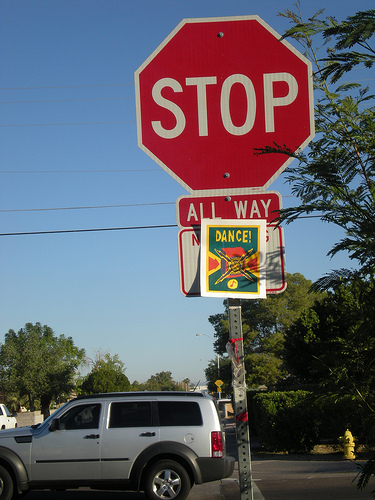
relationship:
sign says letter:
[133, 10, 317, 192] [151, 72, 298, 139]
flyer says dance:
[199, 216, 269, 302] [213, 227, 253, 245]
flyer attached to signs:
[199, 216, 269, 302] [174, 190, 290, 295]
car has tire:
[1, 387, 237, 499] [139, 456, 193, 499]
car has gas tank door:
[1, 387, 237, 499] [181, 430, 197, 445]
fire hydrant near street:
[336, 427, 358, 463] [237, 455, 373, 500]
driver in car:
[84, 405, 100, 430] [1, 387, 237, 499]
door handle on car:
[82, 432, 102, 441] [1, 387, 237, 499]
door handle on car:
[138, 430, 158, 440] [1, 387, 237, 499]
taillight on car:
[210, 430, 222, 460] [1, 387, 237, 499]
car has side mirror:
[1, 387, 237, 499] [45, 414, 63, 432]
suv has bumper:
[1, 387, 237, 499] [194, 453, 239, 482]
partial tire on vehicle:
[2, 462, 19, 499] [1, 387, 237, 499]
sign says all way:
[176, 193, 288, 231] [186, 198, 273, 220]